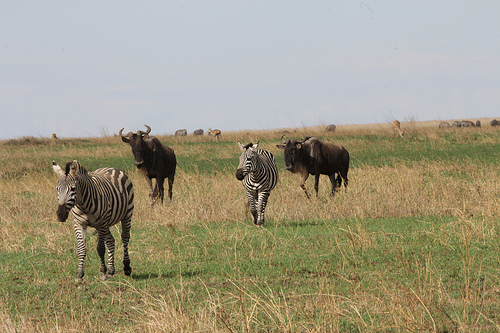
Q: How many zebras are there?
A: Two.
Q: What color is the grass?
A: Green and yellow.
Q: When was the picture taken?
A: Daytime.